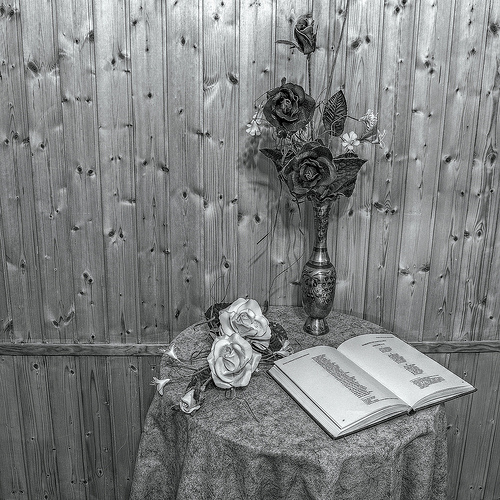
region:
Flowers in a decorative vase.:
[242, 11, 387, 334]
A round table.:
[152, 303, 444, 463]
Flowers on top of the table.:
[150, 300, 285, 418]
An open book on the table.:
[268, 331, 474, 437]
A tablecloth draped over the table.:
[126, 301, 446, 499]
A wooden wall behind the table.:
[3, 243, 498, 498]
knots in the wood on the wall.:
[7, 248, 497, 441]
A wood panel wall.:
[6, 240, 496, 495]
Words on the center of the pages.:
[277, 326, 442, 408]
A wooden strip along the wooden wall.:
[5, 335, 495, 359]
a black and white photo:
[53, 103, 479, 418]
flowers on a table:
[123, 91, 405, 419]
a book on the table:
[246, 324, 443, 454]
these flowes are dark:
[243, 90, 368, 205]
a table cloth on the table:
[118, 325, 493, 498]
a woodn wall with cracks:
[25, 126, 187, 306]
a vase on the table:
[287, 206, 355, 326]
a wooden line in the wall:
[10, 311, 167, 375]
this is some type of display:
[124, 123, 446, 444]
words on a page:
[195, 304, 482, 446]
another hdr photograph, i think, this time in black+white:
[1, 1, 499, 498]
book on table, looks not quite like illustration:
[265, 327, 482, 441]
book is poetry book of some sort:
[268, 326, 481, 440]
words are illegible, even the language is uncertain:
[308, 341, 446, 403]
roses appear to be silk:
[142, 10, 389, 428]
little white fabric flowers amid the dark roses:
[245, 115, 365, 160]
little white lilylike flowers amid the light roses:
[143, 337, 197, 403]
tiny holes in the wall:
[75, 158, 107, 181]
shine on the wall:
[49, 68, 183, 204]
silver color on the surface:
[36, 150, 235, 280]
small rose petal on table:
[177, 393, 204, 414]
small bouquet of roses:
[176, 295, 284, 395]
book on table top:
[285, 318, 490, 448]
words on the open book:
[310, 352, 373, 411]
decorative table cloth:
[138, 426, 291, 473]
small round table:
[153, 308, 457, 479]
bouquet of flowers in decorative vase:
[246, 25, 386, 357]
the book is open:
[300, 335, 462, 428]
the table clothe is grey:
[203, 403, 312, 497]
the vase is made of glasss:
[300, 221, 338, 337]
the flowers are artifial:
[200, 293, 282, 398]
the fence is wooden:
[3, 205, 138, 488]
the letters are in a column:
[311, 346, 388, 426]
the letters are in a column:
[363, 338, 436, 391]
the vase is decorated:
[301, 233, 341, 318]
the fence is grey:
[21, 209, 123, 499]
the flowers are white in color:
[218, 296, 274, 383]